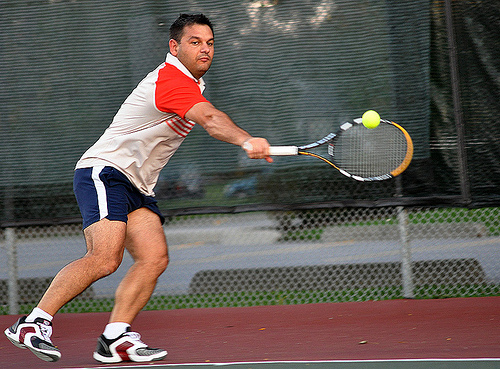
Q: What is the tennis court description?
A: Red surface.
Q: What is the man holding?
A: Tennis racket.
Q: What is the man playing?
A: Tennis.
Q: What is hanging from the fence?
A: Green mesh.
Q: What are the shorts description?
A: Blue and white.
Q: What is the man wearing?
A: Red and white polo shirt.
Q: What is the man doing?
A: Playing tennis.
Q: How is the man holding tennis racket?
A: In right hand.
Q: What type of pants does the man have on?
A: Shorts.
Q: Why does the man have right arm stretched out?
A: To swing racket.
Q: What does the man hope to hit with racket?
A: Tennis ball.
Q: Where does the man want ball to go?
A: Over the net.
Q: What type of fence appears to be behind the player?
A: Chain link.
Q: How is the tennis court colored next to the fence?
A: In red.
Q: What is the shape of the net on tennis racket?
A: Oval.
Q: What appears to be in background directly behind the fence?
A: Sidewalk.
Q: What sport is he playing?
A: Tennis.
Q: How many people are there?
A: One.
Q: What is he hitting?
A: A tennis ball.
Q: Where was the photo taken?
A: Tennis court.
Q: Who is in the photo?
A: A tennis player.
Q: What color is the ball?
A: Yellow.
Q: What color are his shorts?
A: Blue.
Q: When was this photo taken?
A: During the day.